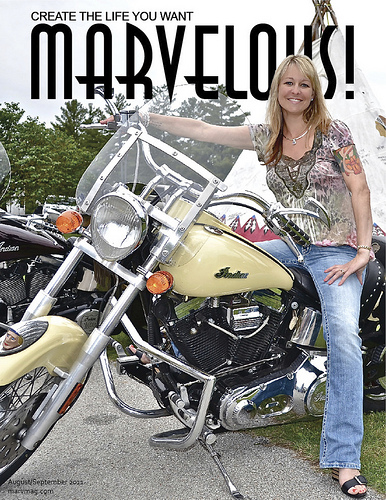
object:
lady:
[99, 55, 372, 499]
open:
[217, 30, 337, 150]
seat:
[288, 247, 385, 298]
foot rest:
[200, 434, 247, 500]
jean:
[251, 240, 367, 472]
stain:
[83, 413, 122, 428]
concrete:
[74, 418, 135, 479]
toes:
[348, 485, 367, 495]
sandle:
[331, 464, 368, 498]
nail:
[354, 476, 366, 485]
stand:
[197, 426, 248, 499]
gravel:
[96, 437, 113, 445]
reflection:
[139, 145, 162, 174]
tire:
[0, 366, 63, 487]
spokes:
[18, 371, 55, 401]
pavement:
[62, 402, 131, 468]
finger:
[323, 262, 363, 286]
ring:
[341, 269, 346, 274]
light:
[146, 271, 173, 294]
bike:
[1, 85, 385, 498]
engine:
[165, 296, 327, 431]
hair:
[261, 55, 333, 170]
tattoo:
[334, 144, 364, 176]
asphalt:
[44, 418, 107, 490]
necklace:
[282, 124, 312, 145]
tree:
[0, 90, 123, 204]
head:
[2, 329, 23, 350]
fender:
[0, 315, 89, 390]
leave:
[60, 103, 104, 154]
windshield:
[75, 85, 256, 268]